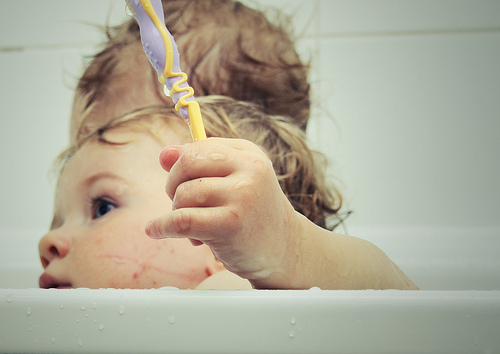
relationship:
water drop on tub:
[309, 285, 323, 293] [0, 283, 499, 354]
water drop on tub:
[285, 312, 304, 329] [0, 283, 499, 354]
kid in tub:
[37, 93, 416, 289] [0, 283, 499, 354]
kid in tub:
[64, 3, 312, 151] [0, 283, 499, 354]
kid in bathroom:
[37, 93, 416, 289] [2, 2, 499, 353]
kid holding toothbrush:
[37, 93, 416, 289] [124, 1, 211, 145]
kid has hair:
[37, 93, 416, 289] [46, 91, 356, 233]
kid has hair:
[64, 3, 312, 151] [66, 16, 319, 140]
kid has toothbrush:
[37, 93, 416, 289] [124, 1, 211, 145]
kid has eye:
[37, 93, 416, 289] [81, 186, 128, 225]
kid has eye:
[37, 93, 416, 289] [46, 212, 71, 233]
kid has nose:
[37, 93, 416, 289] [31, 225, 78, 265]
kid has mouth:
[37, 93, 416, 289] [32, 269, 79, 290]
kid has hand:
[37, 93, 416, 289] [137, 129, 298, 279]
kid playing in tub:
[37, 93, 416, 289] [0, 283, 499, 354]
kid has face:
[37, 93, 416, 289] [31, 153, 218, 292]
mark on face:
[124, 265, 146, 285] [31, 153, 218, 292]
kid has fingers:
[37, 93, 416, 289] [145, 134, 232, 251]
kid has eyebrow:
[37, 93, 416, 289] [78, 170, 133, 190]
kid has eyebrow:
[37, 93, 416, 289] [47, 210, 62, 228]